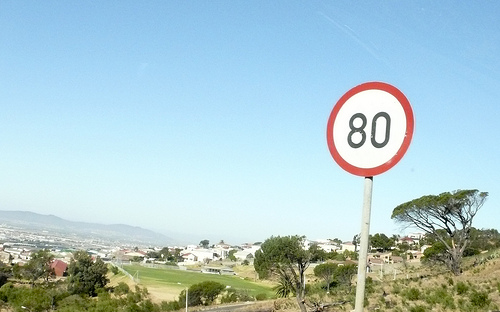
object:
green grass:
[147, 263, 188, 288]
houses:
[174, 244, 221, 264]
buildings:
[44, 258, 68, 277]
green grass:
[122, 262, 281, 302]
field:
[0, 186, 499, 311]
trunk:
[279, 266, 313, 311]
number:
[369, 111, 391, 148]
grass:
[177, 264, 206, 278]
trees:
[66, 249, 111, 298]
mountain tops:
[0, 210, 62, 221]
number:
[347, 112, 369, 149]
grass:
[220, 277, 278, 294]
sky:
[0, 0, 499, 240]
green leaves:
[261, 243, 296, 266]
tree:
[313, 259, 344, 295]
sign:
[324, 81, 414, 177]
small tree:
[252, 233, 325, 300]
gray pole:
[353, 177, 372, 311]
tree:
[390, 187, 490, 276]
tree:
[177, 280, 225, 308]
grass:
[116, 260, 182, 278]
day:
[0, 0, 499, 232]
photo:
[0, 0, 499, 311]